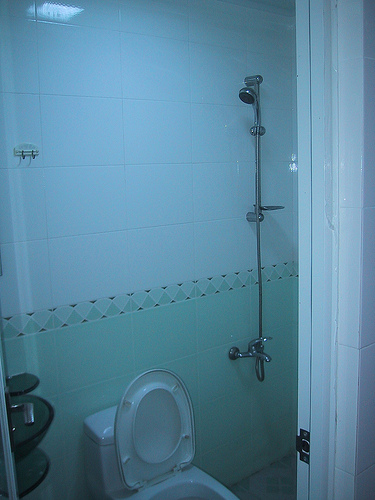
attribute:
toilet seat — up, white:
[101, 343, 242, 477]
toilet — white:
[71, 369, 249, 494]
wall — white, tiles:
[5, 3, 373, 411]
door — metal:
[0, 155, 27, 500]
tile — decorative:
[10, 39, 317, 342]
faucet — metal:
[221, 318, 303, 404]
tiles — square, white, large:
[12, 7, 297, 385]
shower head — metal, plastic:
[221, 67, 276, 131]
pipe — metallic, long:
[234, 58, 287, 380]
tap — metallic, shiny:
[234, 321, 287, 379]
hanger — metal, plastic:
[12, 128, 54, 186]